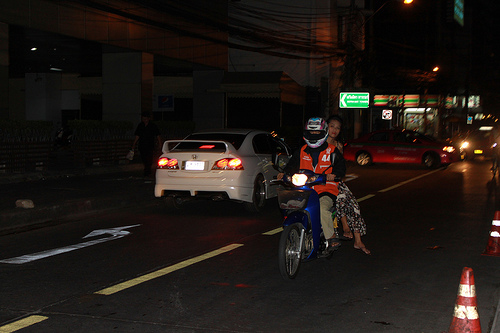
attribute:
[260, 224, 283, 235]
line — yellow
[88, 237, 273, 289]
line — broker, yellow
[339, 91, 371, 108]
sign — traffic sign, business sign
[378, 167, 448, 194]
line — yellow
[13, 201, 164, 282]
arrow — white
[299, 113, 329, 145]
helmet — white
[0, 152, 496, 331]
street — dark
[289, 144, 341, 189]
vest — orange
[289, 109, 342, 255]
passenger — sideways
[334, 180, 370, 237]
skirt — long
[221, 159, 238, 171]
lights — red, yellow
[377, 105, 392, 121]
sign — no turning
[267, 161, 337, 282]
bike — back 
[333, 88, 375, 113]
green sign — green  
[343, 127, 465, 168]
car — red 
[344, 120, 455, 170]
car — red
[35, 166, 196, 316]
road — black